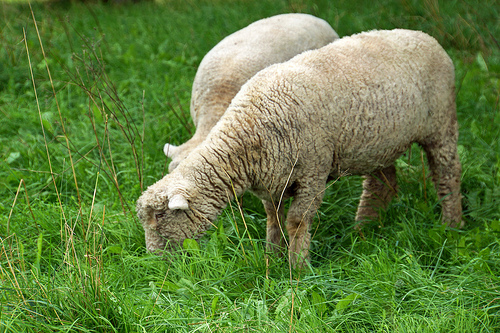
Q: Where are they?
A: In a field.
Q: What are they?
A: Sheep.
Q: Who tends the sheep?
A: A farmer or his hand.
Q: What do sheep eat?
A: Grasses.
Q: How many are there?
A: 2.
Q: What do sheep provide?
A: Wool.